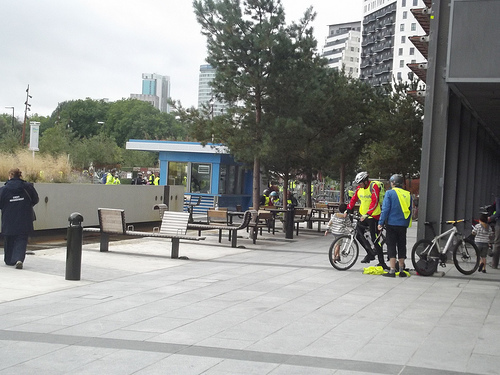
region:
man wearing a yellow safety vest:
[353, 185, 385, 217]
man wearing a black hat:
[385, 169, 406, 188]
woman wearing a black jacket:
[5, 180, 37, 240]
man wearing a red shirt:
[346, 181, 383, 212]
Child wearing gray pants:
[474, 217, 495, 272]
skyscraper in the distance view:
[136, 59, 178, 112]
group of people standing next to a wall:
[93, 160, 159, 180]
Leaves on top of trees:
[213, 28, 421, 176]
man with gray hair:
[386, 171, 411, 196]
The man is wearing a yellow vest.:
[353, 192, 388, 212]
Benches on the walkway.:
[94, 204, 204, 261]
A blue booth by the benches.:
[153, 135, 263, 212]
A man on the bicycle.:
[336, 184, 393, 273]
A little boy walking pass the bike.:
[466, 199, 485, 272]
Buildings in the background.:
[284, 9, 423, 84]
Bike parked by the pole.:
[415, 201, 476, 285]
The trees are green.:
[245, 65, 353, 153]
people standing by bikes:
[324, 175, 418, 287]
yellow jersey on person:
[385, 189, 407, 223]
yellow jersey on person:
[348, 188, 379, 220]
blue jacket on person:
[375, 196, 403, 226]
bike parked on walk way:
[404, 218, 489, 282]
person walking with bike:
[328, 163, 389, 278]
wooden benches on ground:
[101, 203, 202, 271]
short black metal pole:
[55, 208, 92, 289]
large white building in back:
[361, 8, 419, 108]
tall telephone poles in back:
[17, 79, 38, 113]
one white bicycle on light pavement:
[410, 216, 482, 293]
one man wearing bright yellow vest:
[348, 169, 384, 220]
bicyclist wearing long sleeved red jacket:
[328, 167, 383, 271]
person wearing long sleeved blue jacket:
[378, 176, 414, 229]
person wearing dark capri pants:
[379, 172, 410, 276]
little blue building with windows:
[125, 135, 253, 215]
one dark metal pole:
[66, 209, 86, 281]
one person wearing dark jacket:
[1, 160, 38, 233]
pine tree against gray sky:
[133, 1, 305, 107]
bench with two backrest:
[81, 205, 211, 260]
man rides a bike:
[324, 167, 384, 274]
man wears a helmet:
[319, 169, 381, 275]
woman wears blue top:
[374, 170, 418, 282]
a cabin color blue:
[123, 130, 265, 227]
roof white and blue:
[119, 132, 249, 156]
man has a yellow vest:
[342, 167, 384, 227]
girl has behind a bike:
[464, 208, 495, 278]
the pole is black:
[59, 207, 89, 284]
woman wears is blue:
[1, 162, 42, 272]